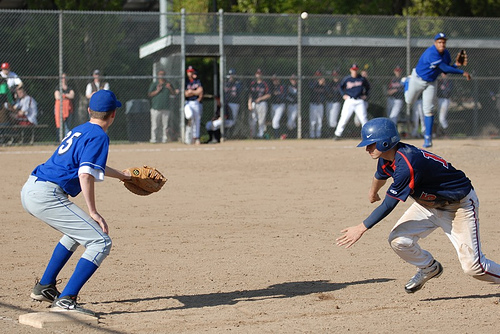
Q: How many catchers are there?
A: Two.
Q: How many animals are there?
A: None.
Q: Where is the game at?
A: Baseball field.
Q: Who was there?
A: Baseball players.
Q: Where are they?
A: Baseball field.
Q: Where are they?
A: Baseball field.